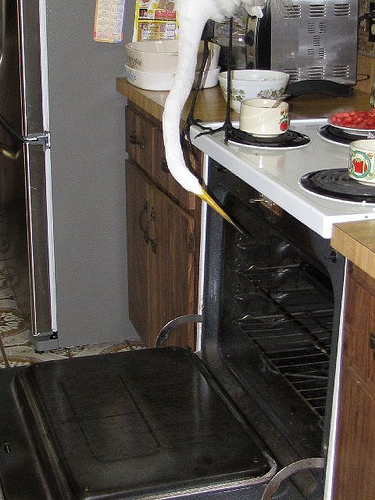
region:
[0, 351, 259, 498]
open oven door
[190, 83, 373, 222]
metal gas stove top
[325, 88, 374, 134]
white plate with tomatoes on a gas burner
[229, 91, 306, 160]
white with flowers cup sitting on gas burner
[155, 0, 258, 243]
white crane neck looking into the open oven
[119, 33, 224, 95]
dishes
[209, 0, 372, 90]
silver and black microwave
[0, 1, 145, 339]
gray and black refrigerator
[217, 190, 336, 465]
black oven racks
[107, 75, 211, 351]
brown kitchen cabinet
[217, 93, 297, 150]
cup on stove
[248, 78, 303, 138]
metal spoon in cup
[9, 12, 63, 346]
fridge door is closed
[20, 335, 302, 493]
oven door is open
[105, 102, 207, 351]
brown cabinets in kitchen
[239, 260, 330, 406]
metal grates in the oven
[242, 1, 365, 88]
toaster oven on the counterop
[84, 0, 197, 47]
stickers on the fridge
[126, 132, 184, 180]
black handles on the drawer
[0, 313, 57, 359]
pattern on tile floor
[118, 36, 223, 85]
The white containers on the counter.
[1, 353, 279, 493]
The open oven door.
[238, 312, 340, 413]
The bottom rack in the oven.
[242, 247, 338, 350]
The top rack in the oven.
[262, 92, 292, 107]
The utensil in the bowl on the stove.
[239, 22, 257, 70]
The knobs on the toaster oven.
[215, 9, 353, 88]
The toaster oven on the counter.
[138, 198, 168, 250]
The handles on the cabinets below the counter.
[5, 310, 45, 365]
The designed tiles of the floor.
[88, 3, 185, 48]
The yellow papers on the wall.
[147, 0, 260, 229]
white bird looking in oven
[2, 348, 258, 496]
open black door of oven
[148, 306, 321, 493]
silver hinges of oven door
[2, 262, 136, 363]
patterned flooring in kitchen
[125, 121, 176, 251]
black handles on bottom cabinets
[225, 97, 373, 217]
black burners of stovetop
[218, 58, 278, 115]
bowl sitting on countertop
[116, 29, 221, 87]
stacked casserole dishes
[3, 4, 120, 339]
side of fridge in kitchen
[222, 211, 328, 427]
two racks inside of black oven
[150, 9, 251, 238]
long neck of a white bird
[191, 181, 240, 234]
yellow beak of a bird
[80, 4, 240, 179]
white feather so a bird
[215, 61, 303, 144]
bowl sitting on counter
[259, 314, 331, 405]
black rack inside overn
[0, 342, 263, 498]
open black oven door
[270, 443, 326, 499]
metal hing on side of oven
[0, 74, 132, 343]
silver fridge by cabinet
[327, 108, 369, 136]
plate with red food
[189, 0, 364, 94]
silver and black toaster oven